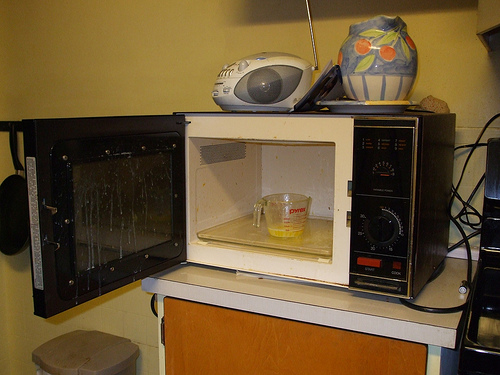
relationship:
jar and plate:
[338, 14, 420, 102] [313, 98, 417, 115]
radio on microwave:
[212, 51, 315, 114] [18, 109, 457, 320]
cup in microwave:
[253, 191, 313, 241] [18, 109, 457, 320]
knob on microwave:
[365, 212, 396, 243] [18, 109, 457, 320]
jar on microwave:
[338, 14, 420, 102] [18, 109, 457, 320]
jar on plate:
[338, 14, 420, 102] [313, 98, 417, 115]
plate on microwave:
[313, 98, 417, 115] [18, 109, 457, 320]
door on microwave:
[19, 114, 188, 319] [18, 109, 457, 320]